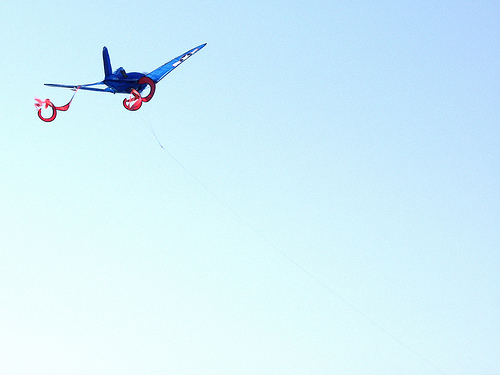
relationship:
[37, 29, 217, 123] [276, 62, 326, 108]
plane in sky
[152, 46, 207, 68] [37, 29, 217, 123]
wing of plane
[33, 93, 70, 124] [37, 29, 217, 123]
flag hanging from plane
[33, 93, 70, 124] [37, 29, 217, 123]
ribbons on plane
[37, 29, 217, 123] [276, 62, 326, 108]
kite in sky